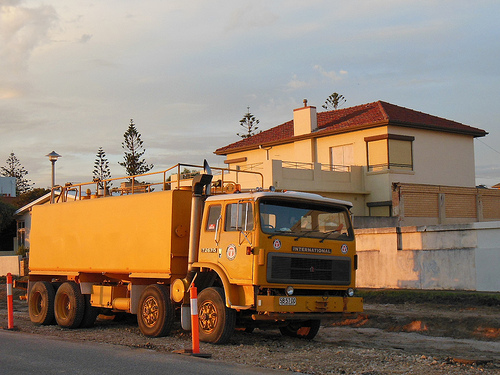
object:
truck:
[27, 173, 366, 344]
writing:
[286, 246, 335, 254]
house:
[211, 97, 498, 226]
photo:
[0, 1, 498, 370]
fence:
[348, 220, 500, 294]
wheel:
[26, 282, 55, 326]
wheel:
[194, 285, 230, 345]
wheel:
[281, 322, 321, 340]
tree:
[0, 150, 36, 204]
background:
[0, 0, 498, 374]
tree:
[89, 145, 113, 196]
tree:
[116, 117, 154, 191]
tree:
[233, 103, 258, 137]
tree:
[320, 91, 347, 110]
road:
[0, 325, 499, 374]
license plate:
[275, 295, 302, 305]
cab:
[196, 189, 364, 345]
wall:
[350, 227, 496, 296]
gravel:
[0, 298, 499, 374]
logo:
[225, 244, 237, 261]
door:
[199, 199, 259, 281]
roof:
[210, 100, 489, 158]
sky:
[0, 0, 498, 189]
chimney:
[290, 99, 318, 135]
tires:
[136, 284, 169, 337]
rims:
[189, 287, 227, 342]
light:
[43, 148, 63, 164]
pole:
[49, 162, 56, 204]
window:
[255, 203, 355, 240]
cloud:
[0, 0, 499, 186]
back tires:
[53, 281, 90, 326]